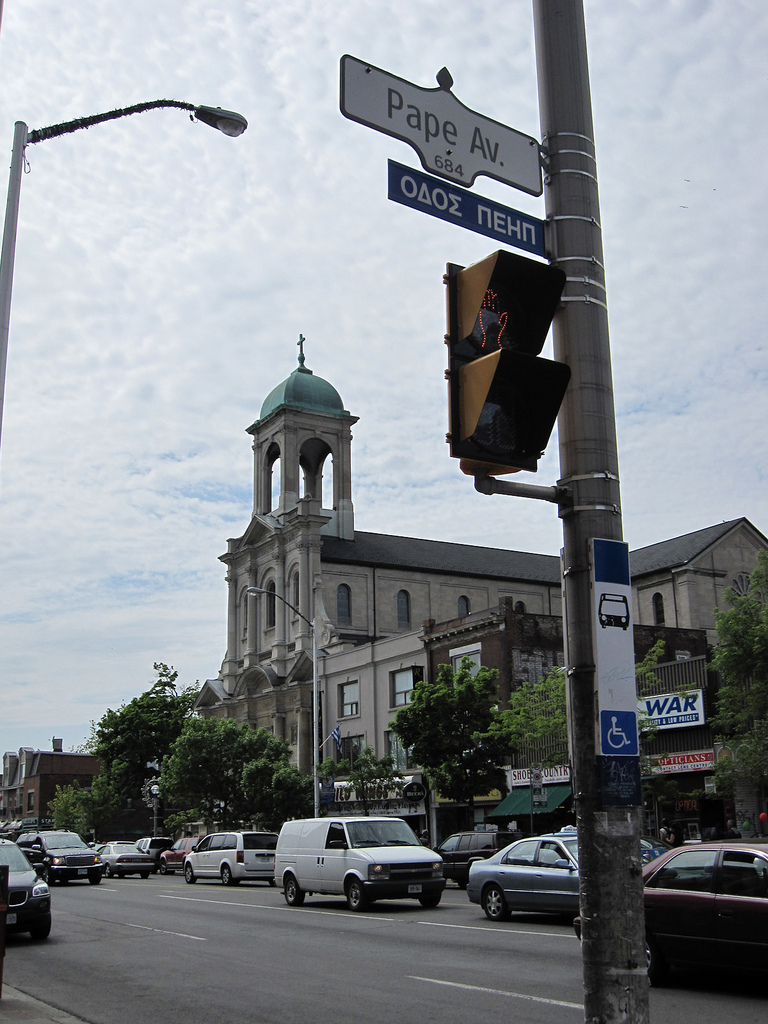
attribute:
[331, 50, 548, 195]
sign — white, grey, black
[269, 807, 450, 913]
van — white, large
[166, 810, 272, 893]
van — white, small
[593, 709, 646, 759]
handicapped sign — blue, square shaped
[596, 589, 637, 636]
bus outline — black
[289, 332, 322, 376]
cross — grey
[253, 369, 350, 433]
dome — green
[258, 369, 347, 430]
dome — green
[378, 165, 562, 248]
sign — blue, white, rectangular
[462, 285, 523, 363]
hand symbol — orange, LED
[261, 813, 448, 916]
van — white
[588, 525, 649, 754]
sign — blue, white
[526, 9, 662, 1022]
pole — metal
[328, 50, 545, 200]
street sign — white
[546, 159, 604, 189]
brackets — silver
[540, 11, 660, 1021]
pole — gray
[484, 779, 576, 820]
awning — green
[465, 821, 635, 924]
car — silver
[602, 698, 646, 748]
handicap sign — blue, white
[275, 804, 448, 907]
van — white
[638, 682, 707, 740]
sign — white, blue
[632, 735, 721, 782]
sign — red, white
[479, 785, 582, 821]
awning — green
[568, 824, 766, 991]
car — red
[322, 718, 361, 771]
flag — blue, white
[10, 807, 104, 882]
vehicle — black